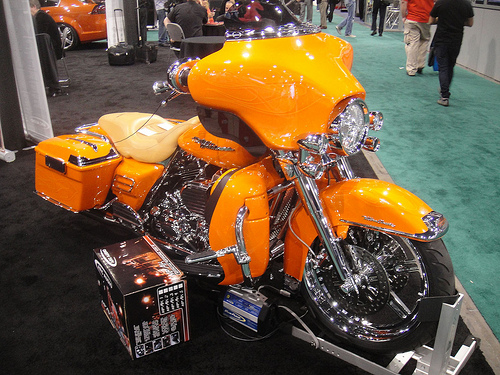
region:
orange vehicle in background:
[34, 0, 114, 52]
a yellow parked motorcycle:
[31, 19, 458, 356]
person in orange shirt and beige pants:
[400, 0, 442, 78]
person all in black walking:
[425, 1, 476, 100]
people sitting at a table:
[163, 0, 233, 59]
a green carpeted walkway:
[299, 6, 499, 342]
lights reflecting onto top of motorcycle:
[229, 27, 319, 70]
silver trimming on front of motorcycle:
[279, 99, 386, 295]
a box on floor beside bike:
[91, 231, 191, 363]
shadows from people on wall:
[461, 32, 498, 79]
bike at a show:
[39, 26, 464, 353]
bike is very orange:
[195, 40, 367, 158]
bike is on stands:
[295, 283, 482, 371]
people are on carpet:
[383, 7, 482, 132]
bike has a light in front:
[330, 92, 366, 149]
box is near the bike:
[83, 237, 197, 351]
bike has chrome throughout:
[161, 179, 208, 271]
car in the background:
[35, 0, 118, 44]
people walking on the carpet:
[396, 3, 476, 109]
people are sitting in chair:
[161, 0, 205, 68]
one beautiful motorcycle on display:
[30, 16, 462, 366]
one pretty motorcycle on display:
[20, 16, 463, 345]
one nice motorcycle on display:
[25, 26, 479, 351]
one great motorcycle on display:
[20, 15, 470, 340]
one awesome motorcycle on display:
[7, 18, 479, 355]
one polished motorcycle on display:
[33, 14, 462, 349]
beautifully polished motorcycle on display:
[28, 25, 463, 358]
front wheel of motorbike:
[292, 183, 452, 353]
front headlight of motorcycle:
[322, 87, 382, 175]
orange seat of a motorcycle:
[87, 93, 187, 168]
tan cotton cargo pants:
[398, 20, 435, 77]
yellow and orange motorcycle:
[33, 26, 458, 365]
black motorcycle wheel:
[291, 187, 454, 359]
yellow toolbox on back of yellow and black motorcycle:
[28, 123, 115, 211]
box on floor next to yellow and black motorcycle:
[81, 235, 196, 362]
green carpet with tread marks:
[403, 118, 489, 195]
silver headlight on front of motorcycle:
[323, 93, 373, 160]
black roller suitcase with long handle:
[101, 4, 141, 64]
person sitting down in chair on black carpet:
[27, 2, 75, 89]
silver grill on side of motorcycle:
[178, 180, 207, 217]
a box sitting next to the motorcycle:
[90, 232, 190, 360]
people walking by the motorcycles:
[401, 0, 477, 107]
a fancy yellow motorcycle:
[32, 34, 449, 360]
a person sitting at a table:
[158, 2, 208, 42]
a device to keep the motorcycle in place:
[278, 285, 478, 373]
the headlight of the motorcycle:
[330, 104, 367, 151]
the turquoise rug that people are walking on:
[331, 19, 498, 340]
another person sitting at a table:
[31, 4, 68, 73]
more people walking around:
[296, 0, 402, 35]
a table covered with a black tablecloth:
[180, 28, 225, 57]